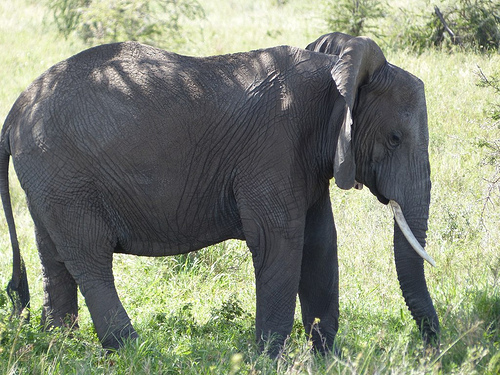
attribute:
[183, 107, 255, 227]
flesh — saggy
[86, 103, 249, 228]
skin — rough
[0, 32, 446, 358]
elephant — grey, standing, gray, African, walking, alone, big,  lone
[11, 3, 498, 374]
grass — clump, green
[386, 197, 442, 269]
tusk — white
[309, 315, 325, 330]
flower — yellow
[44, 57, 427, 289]
wrinkles — large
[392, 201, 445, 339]
trunk — gray, long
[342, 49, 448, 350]
head — gray